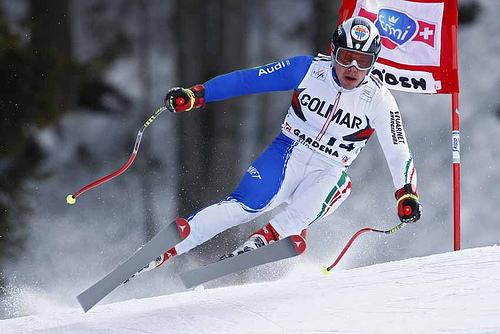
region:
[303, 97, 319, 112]
black letter on ski suit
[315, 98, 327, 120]
black letter on ski suit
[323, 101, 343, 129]
black letter on ski suit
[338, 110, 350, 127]
black letter on ski suit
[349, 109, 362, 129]
black letter on ski suit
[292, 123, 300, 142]
black letter on ski suit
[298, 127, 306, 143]
black letter on ski suit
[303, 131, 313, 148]
black letter on ski suit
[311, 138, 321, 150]
black letter on ski suit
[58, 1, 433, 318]
a downhill skier competing in a race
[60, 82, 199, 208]
competition ski poles are angled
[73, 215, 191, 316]
the skier's skis are tipped with red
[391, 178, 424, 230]
the skier wears black and red gloves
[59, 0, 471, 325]
looks like the skier has just rounded a gate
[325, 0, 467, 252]
flags in competitive races are called gates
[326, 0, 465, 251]
the logo on the flag indicates this race could be in Switzerland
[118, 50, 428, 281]
the skier's outfit is white and blue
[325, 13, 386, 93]
the skier is wearing a helmet and goggles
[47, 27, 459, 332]
skier using bent poles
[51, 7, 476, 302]
competitive skier in a race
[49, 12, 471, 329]
skier going around a flag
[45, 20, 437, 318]
the skier is sponsered by audi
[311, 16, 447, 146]
skier has helmet on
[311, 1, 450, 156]
skier has googles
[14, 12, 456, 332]
skier goes around a turn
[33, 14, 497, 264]
the skier wears white and blue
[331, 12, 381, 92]
man wearing black and silver helmet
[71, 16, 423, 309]
skier wearing blue and white ski suit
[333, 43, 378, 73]
orange tinted ski goggles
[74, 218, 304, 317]
bottom of two skis in snow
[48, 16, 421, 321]
skier holding two red ski poles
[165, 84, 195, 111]
one black glove gripping red handle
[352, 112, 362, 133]
one black capital letter R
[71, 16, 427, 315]
professional athlete in snow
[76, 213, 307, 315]
gray and red skis in snow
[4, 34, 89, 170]
A tree to the left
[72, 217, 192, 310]
A person has a ski on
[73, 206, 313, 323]
A person has two skis on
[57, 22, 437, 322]
A person is skiing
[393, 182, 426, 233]
A glove on the skiers' hand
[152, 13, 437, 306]
The person has an outfit on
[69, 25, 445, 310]
The person is slightly off the ground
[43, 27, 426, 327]
The person is currently in the air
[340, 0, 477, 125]
Flag behind the skier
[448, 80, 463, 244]
Red pole the sign is on